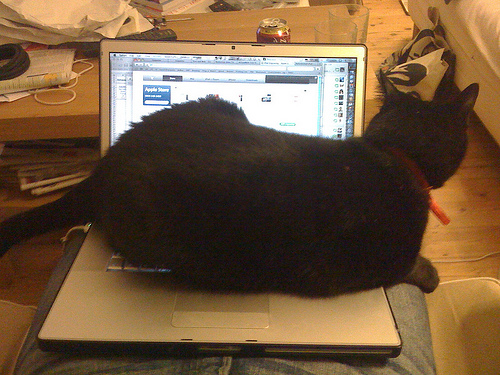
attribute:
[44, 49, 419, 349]
laptop — open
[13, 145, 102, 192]
papers — pile 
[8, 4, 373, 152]
table — under 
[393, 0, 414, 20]
remote — control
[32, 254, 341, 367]
laptop keyboard — silver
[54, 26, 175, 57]
remote — black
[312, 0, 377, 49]
glass — clear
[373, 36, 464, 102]
pillow — throw 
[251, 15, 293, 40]
cola — can, coca 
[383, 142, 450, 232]
collar — red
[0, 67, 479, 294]
cat — black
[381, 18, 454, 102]
bag — black, white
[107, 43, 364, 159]
laptop screen — lit up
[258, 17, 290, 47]
soda can — soda 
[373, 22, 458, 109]
tote bag — black, white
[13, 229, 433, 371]
jeans — blue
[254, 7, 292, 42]
can — red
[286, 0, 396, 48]
glasses — empty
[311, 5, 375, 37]
glass — empty